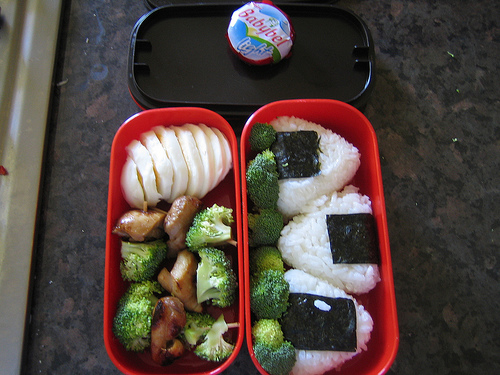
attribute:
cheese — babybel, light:
[224, 0, 298, 69]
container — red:
[239, 95, 402, 375]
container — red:
[101, 103, 246, 375]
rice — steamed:
[267, 109, 365, 218]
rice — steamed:
[276, 179, 383, 294]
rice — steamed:
[278, 264, 378, 375]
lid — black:
[124, 0, 379, 132]